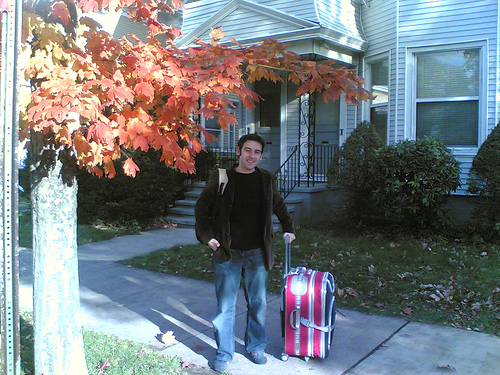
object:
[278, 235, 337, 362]
suitcase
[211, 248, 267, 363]
jeans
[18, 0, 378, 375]
tree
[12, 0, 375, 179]
leaves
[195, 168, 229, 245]
backpack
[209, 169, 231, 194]
shoulder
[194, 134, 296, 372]
man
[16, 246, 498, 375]
sidewalk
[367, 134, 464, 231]
bush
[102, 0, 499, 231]
house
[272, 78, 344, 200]
railing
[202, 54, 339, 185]
porch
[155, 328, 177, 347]
leaf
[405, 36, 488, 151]
window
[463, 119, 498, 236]
bushes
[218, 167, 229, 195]
strap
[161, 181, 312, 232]
stairs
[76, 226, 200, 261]
pathway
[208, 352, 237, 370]
shoes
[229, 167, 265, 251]
shirt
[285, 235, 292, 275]
handle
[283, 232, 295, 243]
hand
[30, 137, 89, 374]
trunk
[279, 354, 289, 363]
wheels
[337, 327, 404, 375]
line